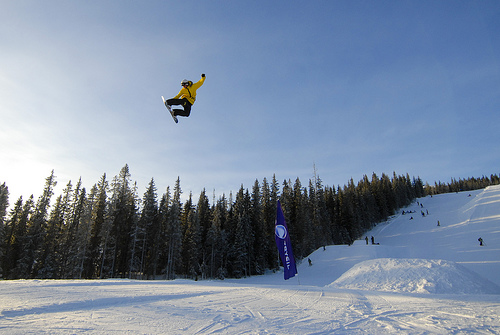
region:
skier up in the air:
[145, 58, 225, 142]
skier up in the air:
[144, 52, 214, 137]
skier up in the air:
[150, 49, 235, 143]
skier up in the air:
[150, 59, 227, 134]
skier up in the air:
[147, 53, 214, 133]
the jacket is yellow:
[172, 80, 207, 107]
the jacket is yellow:
[167, 77, 212, 107]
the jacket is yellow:
[167, 63, 215, 108]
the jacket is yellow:
[172, 85, 204, 111]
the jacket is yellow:
[162, 73, 208, 114]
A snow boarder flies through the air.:
[160, 73, 207, 123]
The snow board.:
[160, 91, 182, 128]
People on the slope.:
[412, 198, 442, 233]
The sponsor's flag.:
[272, 200, 299, 280]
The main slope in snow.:
[468, 187, 492, 299]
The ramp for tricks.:
[331, 257, 494, 297]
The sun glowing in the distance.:
[7, 114, 59, 199]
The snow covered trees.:
[35, 162, 260, 277]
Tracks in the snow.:
[180, 295, 440, 333]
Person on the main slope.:
[475, 235, 487, 246]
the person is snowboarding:
[118, 37, 262, 187]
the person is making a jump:
[81, 20, 243, 187]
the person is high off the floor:
[114, 45, 261, 176]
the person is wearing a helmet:
[171, 71, 198, 95]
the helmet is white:
[167, 71, 193, 91]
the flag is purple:
[228, 174, 313, 295]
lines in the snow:
[268, 290, 443, 331]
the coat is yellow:
[158, 60, 220, 107]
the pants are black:
[151, 92, 191, 121]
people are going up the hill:
[311, 176, 493, 291]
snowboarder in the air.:
[155, 66, 210, 126]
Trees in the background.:
[0, 175, 491, 280]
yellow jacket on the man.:
[156, 71, 206, 106]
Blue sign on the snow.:
[265, 195, 305, 277]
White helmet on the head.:
[175, 75, 191, 90]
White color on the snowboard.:
[157, 92, 177, 127]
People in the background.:
[357, 227, 377, 248]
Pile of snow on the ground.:
[325, 250, 481, 306]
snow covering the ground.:
[1, 181, 491, 331]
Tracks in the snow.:
[177, 292, 494, 333]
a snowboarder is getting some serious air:
[152, 55, 472, 291]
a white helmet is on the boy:
[176, 74, 195, 92]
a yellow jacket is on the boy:
[173, 75, 205, 102]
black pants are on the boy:
[168, 95, 193, 119]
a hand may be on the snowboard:
[156, 88, 179, 110]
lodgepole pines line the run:
[3, 154, 498, 284]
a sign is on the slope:
[266, 200, 303, 278]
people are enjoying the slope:
[306, 176, 493, 281]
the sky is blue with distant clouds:
[12, 0, 499, 210]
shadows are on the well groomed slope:
[19, 185, 499, 334]